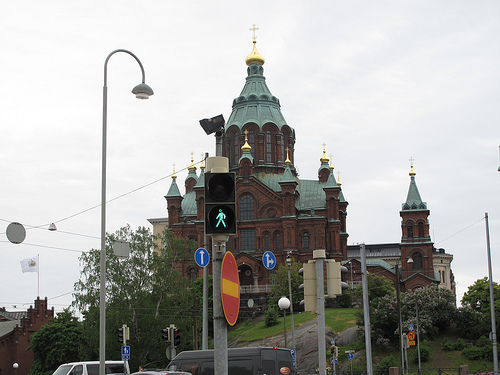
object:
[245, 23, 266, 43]
cross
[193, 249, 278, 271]
signs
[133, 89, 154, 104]
light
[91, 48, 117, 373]
pole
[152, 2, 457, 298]
building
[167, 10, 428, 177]
crosses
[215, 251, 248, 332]
sign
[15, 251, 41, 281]
flag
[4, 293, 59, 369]
building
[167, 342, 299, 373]
van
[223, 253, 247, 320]
caution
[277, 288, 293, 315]
lamp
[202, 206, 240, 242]
crosswalk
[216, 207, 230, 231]
walk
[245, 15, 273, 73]
steeple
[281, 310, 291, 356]
post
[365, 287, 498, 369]
shrubbery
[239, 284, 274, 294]
railing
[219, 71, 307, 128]
roofing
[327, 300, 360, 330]
grass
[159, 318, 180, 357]
traffic light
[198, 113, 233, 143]
camera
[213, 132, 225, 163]
pole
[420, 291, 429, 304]
flowers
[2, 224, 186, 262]
wires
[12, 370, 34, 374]
ground